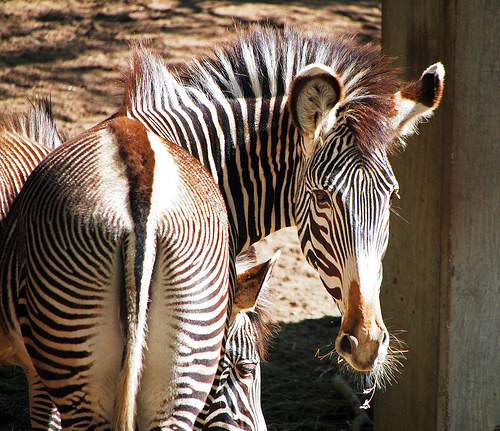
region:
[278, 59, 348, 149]
zebra's right ear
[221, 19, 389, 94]
zebra's black and white mane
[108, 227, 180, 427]
zebra's black and white tail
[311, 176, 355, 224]
zebra's right open eye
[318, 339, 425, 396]
zebra's sparse whiskers under his nose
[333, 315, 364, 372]
zebra's right nostril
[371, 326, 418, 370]
zebra's left nostril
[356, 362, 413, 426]
twig in zebra's mouth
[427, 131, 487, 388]
wooden pole in zebra's enclosure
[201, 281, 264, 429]
second zebra in front of picture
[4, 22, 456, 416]
a group of zebras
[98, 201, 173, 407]
tail on the zebra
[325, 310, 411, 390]
whiskers on the zebra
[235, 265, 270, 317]
ear on the zebra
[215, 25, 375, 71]
mane on the zebra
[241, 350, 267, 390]
eye on the zebra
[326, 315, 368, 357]
nostril on the zebra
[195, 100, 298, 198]
stripes on the zebra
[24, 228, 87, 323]
stripes on the zebra's butt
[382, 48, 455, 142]
ear of a zebra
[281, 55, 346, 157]
ear of a zebra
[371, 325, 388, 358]
nostril of a zebra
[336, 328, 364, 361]
nostril of a zebra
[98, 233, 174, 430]
tail of a zebra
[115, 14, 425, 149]
mane of a zebra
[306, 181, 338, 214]
eye of a zebra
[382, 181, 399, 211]
eye of a zebra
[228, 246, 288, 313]
ear of a zebra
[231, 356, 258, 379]
eye of a zebra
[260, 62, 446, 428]
zebra head with black stripes on the front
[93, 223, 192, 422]
zebra tail with a black stripe going down the middle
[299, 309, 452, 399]
whiskers on the snout of the zebra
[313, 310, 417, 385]
nostrils on the nose of the zebra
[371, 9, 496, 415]
wooden post next to a zebra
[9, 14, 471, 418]
two zebras standing next to each other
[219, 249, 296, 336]
zebra ear with brown markings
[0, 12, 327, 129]
dirt covered ground covered in light and shadows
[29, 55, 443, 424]
zebra with his head turned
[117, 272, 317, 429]
zebra with his head lowered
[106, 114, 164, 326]
stripe on the tail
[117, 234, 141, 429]
the zebra stripes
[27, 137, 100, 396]
the balck and white stripes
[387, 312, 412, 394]
whiskers on the mouth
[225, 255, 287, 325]
the ear of the zebra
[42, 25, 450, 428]
two zebras standing up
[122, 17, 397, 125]
hair on the neck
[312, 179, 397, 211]
the eyes of the zebra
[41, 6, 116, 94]
dirt on the ground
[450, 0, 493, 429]
a wooden wall by the zebra